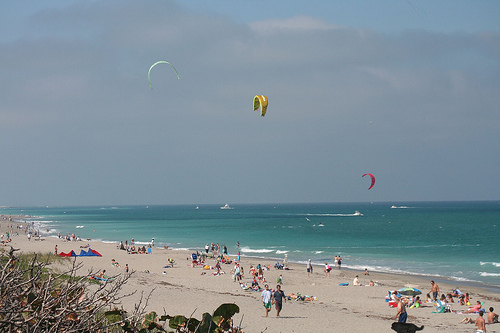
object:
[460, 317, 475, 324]
person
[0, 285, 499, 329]
ground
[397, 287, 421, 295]
umbrella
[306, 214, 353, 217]
wave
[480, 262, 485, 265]
wave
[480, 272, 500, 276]
wave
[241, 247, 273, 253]
wave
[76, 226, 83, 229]
wave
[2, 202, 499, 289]
sea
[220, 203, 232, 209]
boat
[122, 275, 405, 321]
sand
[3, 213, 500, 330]
beach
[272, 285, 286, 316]
person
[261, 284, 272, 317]
person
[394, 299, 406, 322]
person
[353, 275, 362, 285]
person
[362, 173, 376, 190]
kite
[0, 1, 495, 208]
sky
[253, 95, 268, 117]
kite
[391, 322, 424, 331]
dog